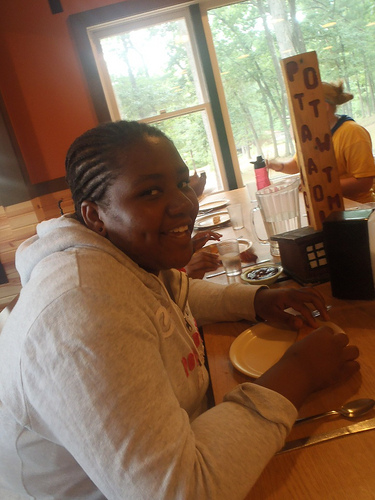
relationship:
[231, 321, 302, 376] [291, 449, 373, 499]
plate on table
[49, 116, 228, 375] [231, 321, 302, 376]
girl near plate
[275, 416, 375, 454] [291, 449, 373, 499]
knife on table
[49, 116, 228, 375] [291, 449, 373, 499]
girl near table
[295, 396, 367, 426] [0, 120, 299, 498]
spoon on side of girl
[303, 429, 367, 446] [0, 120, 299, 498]
fork on side of girl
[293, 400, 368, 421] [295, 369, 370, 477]
spoon on table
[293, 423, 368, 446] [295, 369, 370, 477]
knife on table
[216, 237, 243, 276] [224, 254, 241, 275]
cup of water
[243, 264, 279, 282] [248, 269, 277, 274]
bowl of sauce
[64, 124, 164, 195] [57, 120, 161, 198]
corn rows in hair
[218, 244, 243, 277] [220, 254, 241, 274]
cup of water